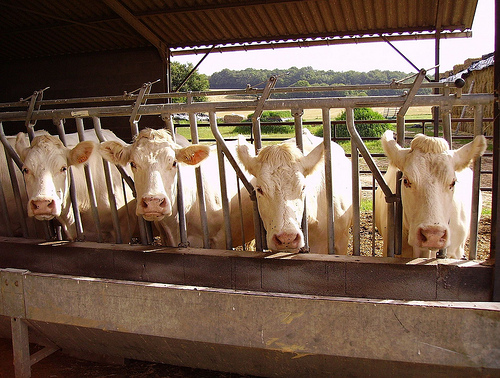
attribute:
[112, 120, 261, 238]
cow — waiting to be fed, white, getting ready to eat, looking at camera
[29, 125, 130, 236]
cow — white, looking at camera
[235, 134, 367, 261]
cow — white, looking at camera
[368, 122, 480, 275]
cow — white, looking at camera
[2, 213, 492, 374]
trough — empty, metal, concrete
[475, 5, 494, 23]
sun — shining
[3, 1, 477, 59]
roof — metal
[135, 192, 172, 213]
nose — pink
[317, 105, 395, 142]
hay — green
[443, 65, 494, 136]
hay — brown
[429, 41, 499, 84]
tarp — black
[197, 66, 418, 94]
forest — green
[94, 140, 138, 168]
ear — tagged